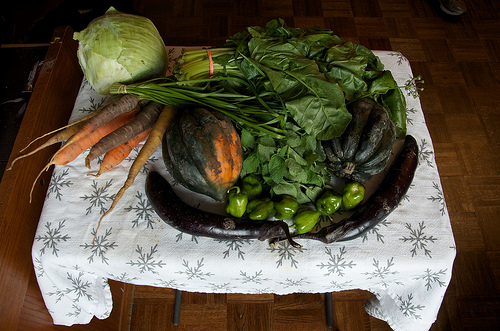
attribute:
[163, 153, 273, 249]
vegetable — black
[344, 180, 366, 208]
pepper — green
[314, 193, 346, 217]
pepper — green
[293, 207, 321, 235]
pepper — green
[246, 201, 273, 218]
pepper — green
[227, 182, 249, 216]
pepper — green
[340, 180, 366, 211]
peppers — green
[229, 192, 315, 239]
peppers — green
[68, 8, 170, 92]
cabbage — green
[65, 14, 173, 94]
cabbage — green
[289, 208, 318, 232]
peppers — green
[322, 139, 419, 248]
eggplant — purple, long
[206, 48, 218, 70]
ribbon — pink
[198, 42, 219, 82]
ribbon — pink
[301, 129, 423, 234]
purple eggplant — long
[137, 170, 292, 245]
purple eggplant — long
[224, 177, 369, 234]
peppers — green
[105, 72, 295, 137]
onion — green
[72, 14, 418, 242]
vegetables — displayed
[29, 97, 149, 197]
carrot — orange, dark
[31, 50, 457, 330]
tablecloth — white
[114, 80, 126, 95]
bands — rubber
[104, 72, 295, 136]
scallions — slender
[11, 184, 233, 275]
cloth — white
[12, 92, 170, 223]
carrots — orange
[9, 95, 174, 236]
carrots — orange and gray, long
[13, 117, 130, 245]
roots — thin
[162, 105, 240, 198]
squash — orange and green, ridged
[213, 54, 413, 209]
leaves — green, ruffled, long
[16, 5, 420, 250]
fruit — raw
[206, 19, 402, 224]
greens — collard